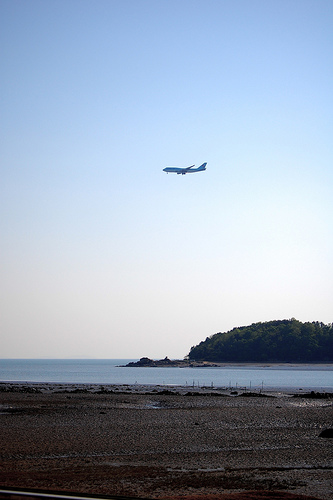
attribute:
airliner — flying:
[161, 162, 206, 174]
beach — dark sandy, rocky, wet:
[3, 382, 331, 494]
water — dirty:
[4, 357, 327, 389]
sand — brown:
[2, 380, 332, 403]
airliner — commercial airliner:
[161, 164, 210, 175]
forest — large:
[187, 317, 331, 364]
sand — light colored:
[10, 388, 324, 481]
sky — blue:
[2, 0, 305, 313]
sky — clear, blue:
[6, 7, 314, 350]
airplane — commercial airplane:
[160, 160, 208, 177]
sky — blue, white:
[1, 1, 330, 361]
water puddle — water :
[137, 395, 169, 408]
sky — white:
[187, 31, 275, 104]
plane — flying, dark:
[161, 160, 209, 176]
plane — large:
[159, 160, 209, 179]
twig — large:
[260, 380, 266, 391]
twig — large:
[248, 377, 254, 388]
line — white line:
[3, 482, 84, 498]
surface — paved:
[1, 481, 99, 498]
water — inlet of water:
[125, 359, 315, 406]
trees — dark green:
[225, 318, 281, 366]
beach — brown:
[12, 389, 301, 465]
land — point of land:
[114, 355, 221, 368]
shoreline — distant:
[206, 357, 329, 369]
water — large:
[0, 356, 117, 384]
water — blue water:
[1, 358, 328, 387]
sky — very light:
[36, 229, 168, 317]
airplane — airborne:
[153, 157, 223, 182]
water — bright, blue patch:
[56, 356, 100, 380]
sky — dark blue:
[4, 5, 329, 63]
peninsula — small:
[117, 315, 331, 366]